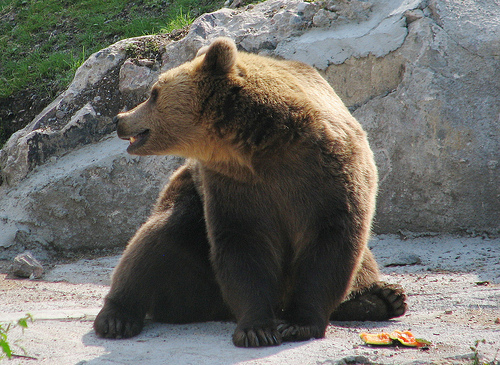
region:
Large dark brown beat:
[65, 17, 390, 364]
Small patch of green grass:
[18, 41, 69, 91]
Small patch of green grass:
[64, 26, 108, 66]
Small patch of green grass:
[105, 8, 164, 39]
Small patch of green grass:
[150, 9, 205, 37]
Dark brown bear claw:
[86, 304, 167, 349]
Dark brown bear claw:
[231, 313, 286, 364]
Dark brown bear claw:
[274, 313, 336, 364]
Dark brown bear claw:
[363, 264, 420, 322]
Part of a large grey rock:
[380, 70, 491, 244]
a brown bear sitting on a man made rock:
[76, 20, 441, 359]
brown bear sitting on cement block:
[92, 35, 400, 364]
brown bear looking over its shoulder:
[110, 35, 374, 186]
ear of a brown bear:
[202, 35, 238, 73]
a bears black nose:
[109, 113, 122, 125]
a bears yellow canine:
[121, 131, 142, 148]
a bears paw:
[229, 314, 284, 355]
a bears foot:
[336, 278, 418, 328]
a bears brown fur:
[161, 56, 398, 246]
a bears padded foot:
[341, 278, 426, 328]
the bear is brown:
[85, 15, 390, 362]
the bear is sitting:
[60, 40, 398, 354]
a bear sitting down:
[40, 19, 430, 364]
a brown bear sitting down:
[71, 41, 398, 354]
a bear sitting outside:
[29, 13, 497, 313]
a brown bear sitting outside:
[58, 27, 463, 361]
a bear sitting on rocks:
[12, 31, 469, 351]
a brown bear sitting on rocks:
[40, 23, 385, 348]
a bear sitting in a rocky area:
[0, 14, 488, 314]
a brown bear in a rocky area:
[60, 37, 449, 358]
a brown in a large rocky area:
[32, 23, 479, 362]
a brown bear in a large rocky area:
[62, 39, 376, 346]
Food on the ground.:
[355, 316, 442, 353]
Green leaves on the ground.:
[7, 309, 44, 356]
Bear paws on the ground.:
[78, 291, 145, 349]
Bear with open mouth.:
[110, 61, 208, 166]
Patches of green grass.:
[22, 5, 100, 60]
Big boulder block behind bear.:
[30, 85, 181, 287]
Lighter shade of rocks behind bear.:
[342, 13, 453, 54]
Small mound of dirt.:
[10, 73, 47, 141]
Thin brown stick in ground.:
[8, 349, 35, 359]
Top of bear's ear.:
[211, 33, 261, 90]